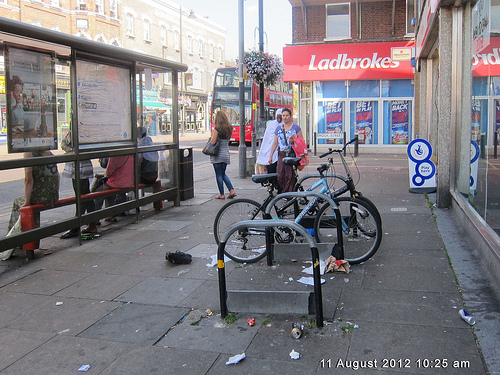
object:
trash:
[164, 249, 190, 267]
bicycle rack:
[213, 192, 342, 323]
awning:
[282, 40, 422, 82]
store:
[283, 0, 433, 160]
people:
[253, 111, 281, 189]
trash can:
[169, 144, 194, 200]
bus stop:
[0, 17, 188, 254]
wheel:
[212, 197, 274, 264]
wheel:
[312, 197, 382, 264]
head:
[280, 107, 293, 124]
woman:
[202, 108, 237, 199]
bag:
[201, 133, 219, 158]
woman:
[271, 109, 311, 194]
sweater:
[289, 132, 311, 167]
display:
[405, 139, 440, 192]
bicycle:
[211, 162, 384, 266]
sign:
[404, 138, 436, 193]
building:
[401, 1, 498, 298]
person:
[60, 115, 97, 237]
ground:
[5, 184, 498, 372]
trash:
[223, 351, 248, 366]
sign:
[282, 41, 414, 81]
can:
[288, 323, 304, 338]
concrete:
[1, 131, 498, 373]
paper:
[205, 254, 231, 268]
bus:
[207, 66, 295, 152]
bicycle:
[264, 134, 382, 238]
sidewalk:
[2, 147, 496, 369]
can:
[457, 304, 478, 325]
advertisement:
[4, 42, 58, 151]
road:
[0, 134, 238, 237]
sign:
[4, 42, 58, 153]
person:
[8, 148, 58, 257]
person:
[89, 151, 135, 231]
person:
[133, 124, 157, 202]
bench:
[13, 179, 161, 259]